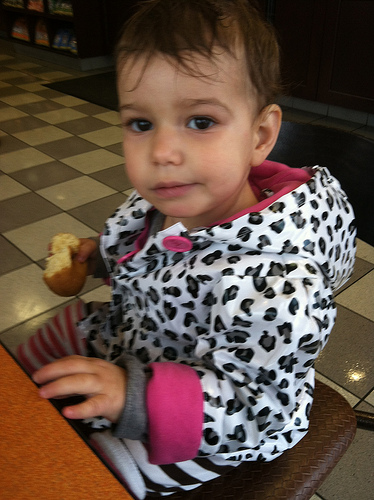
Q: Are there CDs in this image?
A: No, there are no cds.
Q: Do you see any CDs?
A: No, there are no cds.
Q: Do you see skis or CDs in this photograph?
A: No, there are no CDs or skis.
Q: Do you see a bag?
A: No, there are no bags.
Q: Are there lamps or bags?
A: No, there are no bags or lamps.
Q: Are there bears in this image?
A: No, there are no bears.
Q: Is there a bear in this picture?
A: No, there are no bears.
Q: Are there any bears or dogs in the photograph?
A: No, there are no bears or dogs.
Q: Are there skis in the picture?
A: No, there are no skis.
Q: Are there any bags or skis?
A: No, there are no skis or bags.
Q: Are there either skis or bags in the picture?
A: No, there are no skis or bags.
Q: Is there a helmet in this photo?
A: No, there are no helmets.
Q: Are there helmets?
A: No, there are no helmets.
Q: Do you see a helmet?
A: No, there are no helmets.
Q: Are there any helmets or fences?
A: No, there are no helmets or fences.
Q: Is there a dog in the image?
A: No, there are no dogs.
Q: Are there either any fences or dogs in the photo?
A: No, there are no dogs or fences.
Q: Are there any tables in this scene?
A: Yes, there is a table.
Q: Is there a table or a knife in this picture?
A: Yes, there is a table.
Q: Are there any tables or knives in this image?
A: Yes, there is a table.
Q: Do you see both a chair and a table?
A: Yes, there are both a table and a chair.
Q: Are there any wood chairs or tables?
A: Yes, there is a wood table.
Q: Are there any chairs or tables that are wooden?
A: Yes, the table is wooden.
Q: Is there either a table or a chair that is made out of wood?
A: Yes, the table is made of wood.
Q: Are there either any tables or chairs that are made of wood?
A: Yes, the table is made of wood.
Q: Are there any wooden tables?
A: Yes, there is a wood table.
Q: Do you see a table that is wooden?
A: Yes, there is a table that is wooden.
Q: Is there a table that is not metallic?
A: Yes, there is a wooden table.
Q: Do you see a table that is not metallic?
A: Yes, there is a wooden table.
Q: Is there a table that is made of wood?
A: Yes, there is a table that is made of wood.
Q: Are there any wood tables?
A: Yes, there is a table that is made of wood.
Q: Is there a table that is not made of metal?
A: Yes, there is a table that is made of wood.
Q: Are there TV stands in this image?
A: No, there are no TV stands.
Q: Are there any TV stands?
A: No, there are no TV stands.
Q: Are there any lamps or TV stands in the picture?
A: No, there are no TV stands or lamps.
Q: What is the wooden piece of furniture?
A: The piece of furniture is a table.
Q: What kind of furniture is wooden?
A: The furniture is a table.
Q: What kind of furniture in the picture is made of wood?
A: The furniture is a table.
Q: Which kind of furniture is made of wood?
A: The furniture is a table.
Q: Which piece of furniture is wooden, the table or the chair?
A: The table is wooden.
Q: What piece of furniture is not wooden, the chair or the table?
A: The chair is not wooden.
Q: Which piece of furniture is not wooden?
A: The piece of furniture is a chair.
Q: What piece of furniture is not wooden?
A: The piece of furniture is a chair.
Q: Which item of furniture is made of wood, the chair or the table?
A: The table is made of wood.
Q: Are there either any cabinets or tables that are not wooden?
A: No, there is a table but it is wooden.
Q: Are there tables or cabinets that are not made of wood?
A: No, there is a table but it is made of wood.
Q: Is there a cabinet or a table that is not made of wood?
A: No, there is a table but it is made of wood.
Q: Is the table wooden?
A: Yes, the table is wooden.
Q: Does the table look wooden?
A: Yes, the table is wooden.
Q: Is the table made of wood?
A: Yes, the table is made of wood.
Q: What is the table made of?
A: The table is made of wood.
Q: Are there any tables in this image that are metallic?
A: No, there is a table but it is wooden.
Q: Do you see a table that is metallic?
A: No, there is a table but it is wooden.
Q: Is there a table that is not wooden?
A: No, there is a table but it is wooden.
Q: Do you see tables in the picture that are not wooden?
A: No, there is a table but it is wooden.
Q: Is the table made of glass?
A: No, the table is made of wood.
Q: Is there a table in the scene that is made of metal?
A: No, there is a table but it is made of wood.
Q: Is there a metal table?
A: No, there is a table but it is made of wood.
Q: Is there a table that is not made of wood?
A: No, there is a table but it is made of wood.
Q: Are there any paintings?
A: No, there are no paintings.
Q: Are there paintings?
A: No, there are no paintings.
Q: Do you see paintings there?
A: No, there are no paintings.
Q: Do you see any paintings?
A: No, there are no paintings.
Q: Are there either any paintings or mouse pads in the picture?
A: No, there are no paintings or mouse pads.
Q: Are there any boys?
A: No, there are no boys.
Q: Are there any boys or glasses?
A: No, there are no boys or glasses.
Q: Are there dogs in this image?
A: No, there are no dogs.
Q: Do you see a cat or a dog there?
A: No, there are no dogs or cats.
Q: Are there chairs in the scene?
A: Yes, there is a chair.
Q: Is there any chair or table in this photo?
A: Yes, there is a chair.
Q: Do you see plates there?
A: No, there are no plates.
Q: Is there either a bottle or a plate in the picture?
A: No, there are no plates or bottles.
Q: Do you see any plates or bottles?
A: No, there are no plates or bottles.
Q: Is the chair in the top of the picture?
A: No, the chair is in the bottom of the image.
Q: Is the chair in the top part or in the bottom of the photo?
A: The chair is in the bottom of the image.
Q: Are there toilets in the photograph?
A: No, there are no toilets.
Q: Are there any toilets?
A: No, there are no toilets.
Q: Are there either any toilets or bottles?
A: No, there are no toilets or bottles.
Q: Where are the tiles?
A: The tiles are on the floor.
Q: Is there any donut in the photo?
A: Yes, there is a donut.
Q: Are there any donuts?
A: Yes, there is a donut.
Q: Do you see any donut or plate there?
A: Yes, there is a donut.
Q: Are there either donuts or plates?
A: Yes, there is a donut.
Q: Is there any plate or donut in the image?
A: Yes, there is a donut.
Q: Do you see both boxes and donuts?
A: No, there is a donut but no boxes.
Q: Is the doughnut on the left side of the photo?
A: Yes, the doughnut is on the left of the image.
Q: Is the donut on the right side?
A: No, the donut is on the left of the image.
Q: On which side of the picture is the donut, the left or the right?
A: The donut is on the left of the image.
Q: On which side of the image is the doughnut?
A: The doughnut is on the left of the image.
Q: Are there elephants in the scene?
A: No, there are no elephants.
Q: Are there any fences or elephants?
A: No, there are no elephants or fences.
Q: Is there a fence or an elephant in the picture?
A: No, there are no elephants or fences.